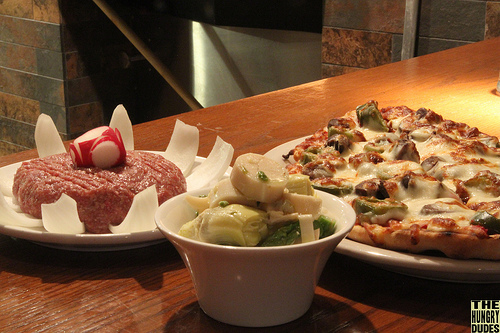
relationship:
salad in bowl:
[197, 168, 314, 241] [199, 256, 284, 309]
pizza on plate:
[364, 128, 462, 221] [366, 249, 429, 274]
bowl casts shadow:
[199, 256, 284, 309] [159, 298, 203, 319]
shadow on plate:
[159, 298, 203, 319] [366, 249, 429, 274]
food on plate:
[71, 126, 406, 227] [366, 249, 429, 274]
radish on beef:
[93, 129, 120, 141] [85, 183, 111, 202]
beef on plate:
[15, 150, 188, 228] [366, 249, 429, 274]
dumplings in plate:
[187, 213, 233, 238] [366, 249, 429, 274]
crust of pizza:
[387, 220, 458, 255] [364, 128, 462, 221]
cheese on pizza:
[402, 191, 428, 208] [364, 128, 462, 221]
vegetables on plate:
[210, 156, 317, 254] [366, 249, 429, 274]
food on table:
[71, 126, 406, 227] [228, 59, 285, 108]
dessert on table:
[113, 112, 231, 154] [228, 59, 285, 108]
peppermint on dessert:
[114, 187, 139, 199] [113, 112, 231, 154]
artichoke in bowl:
[268, 208, 302, 236] [199, 256, 284, 309]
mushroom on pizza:
[425, 149, 442, 182] [364, 128, 462, 221]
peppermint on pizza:
[114, 187, 139, 199] [364, 128, 462, 221]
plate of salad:
[366, 249, 429, 274] [197, 168, 314, 241]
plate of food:
[366, 249, 429, 274] [71, 126, 406, 227]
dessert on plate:
[113, 112, 231, 154] [366, 249, 429, 274]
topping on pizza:
[332, 97, 445, 200] [364, 128, 462, 221]